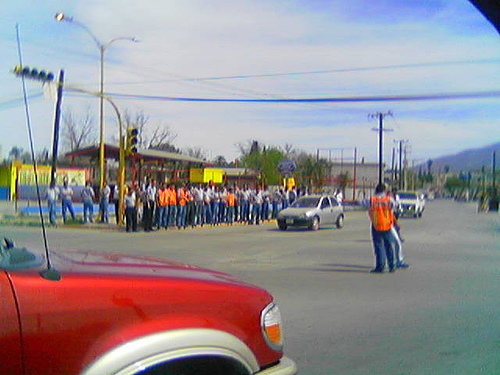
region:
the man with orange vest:
[336, 157, 411, 294]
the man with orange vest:
[323, 166, 439, 368]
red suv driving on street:
[7, 231, 290, 373]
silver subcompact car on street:
[271, 190, 343, 233]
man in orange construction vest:
[366, 185, 397, 265]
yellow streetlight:
[11, 64, 141, 228]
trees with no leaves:
[54, 92, 184, 155]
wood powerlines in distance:
[358, 102, 435, 190]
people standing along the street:
[46, 175, 296, 228]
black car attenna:
[10, 22, 62, 283]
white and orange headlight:
[260, 298, 285, 351]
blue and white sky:
[0, 0, 498, 162]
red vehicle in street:
[0, 263, 314, 373]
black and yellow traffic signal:
[122, 123, 141, 156]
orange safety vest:
[368, 194, 390, 229]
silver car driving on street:
[275, 187, 350, 232]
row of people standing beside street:
[122, 181, 262, 228]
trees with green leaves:
[235, 143, 279, 168]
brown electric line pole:
[377, 112, 384, 180]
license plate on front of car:
[284, 217, 294, 224]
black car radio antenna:
[21, 113, 48, 267]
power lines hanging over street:
[142, 89, 487, 103]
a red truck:
[0, 218, 308, 370]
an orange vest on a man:
[360, 190, 395, 227]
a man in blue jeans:
[370, 220, 400, 266]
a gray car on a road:
[270, 186, 342, 231]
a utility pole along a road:
[365, 105, 405, 210]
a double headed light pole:
[51, 7, 138, 222]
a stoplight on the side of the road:
[118, 118, 138, 160]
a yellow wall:
[5, 155, 94, 198]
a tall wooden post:
[44, 65, 75, 211]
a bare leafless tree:
[61, 107, 95, 159]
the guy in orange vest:
[334, 170, 408, 332]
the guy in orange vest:
[359, 198, 432, 316]